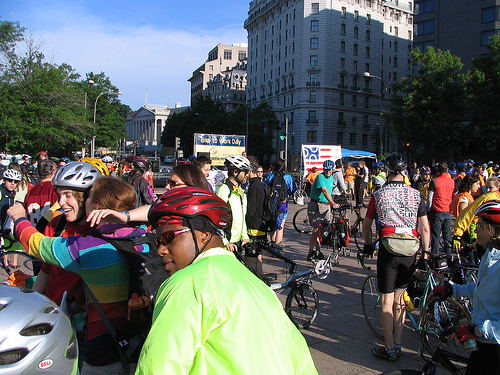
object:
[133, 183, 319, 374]
man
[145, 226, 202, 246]
goggles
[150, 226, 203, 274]
face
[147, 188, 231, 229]
helmet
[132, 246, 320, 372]
jacket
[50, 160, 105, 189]
helmet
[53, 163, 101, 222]
head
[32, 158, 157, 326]
woman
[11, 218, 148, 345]
jacket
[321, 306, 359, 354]
shadow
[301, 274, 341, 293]
ground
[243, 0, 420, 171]
building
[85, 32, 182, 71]
clouds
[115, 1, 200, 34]
sky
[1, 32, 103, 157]
trees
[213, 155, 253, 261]
people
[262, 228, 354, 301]
street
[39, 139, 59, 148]
leaves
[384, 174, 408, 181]
skin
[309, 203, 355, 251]
bike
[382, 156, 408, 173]
helmet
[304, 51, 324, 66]
windows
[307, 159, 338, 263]
man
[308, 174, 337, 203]
shirt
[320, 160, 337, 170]
helmet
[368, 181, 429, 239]
shirt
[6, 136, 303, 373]
crowd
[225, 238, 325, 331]
bikes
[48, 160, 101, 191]
helmets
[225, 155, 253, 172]
helmet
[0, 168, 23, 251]
person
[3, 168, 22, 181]
helmet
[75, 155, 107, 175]
helmet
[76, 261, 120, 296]
stripes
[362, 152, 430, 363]
man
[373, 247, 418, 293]
shorts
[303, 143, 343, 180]
sign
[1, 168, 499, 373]
bicyclists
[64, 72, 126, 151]
tree